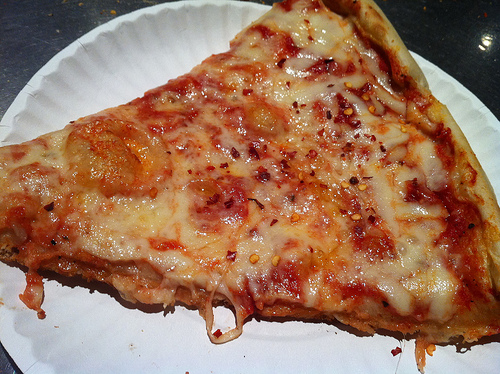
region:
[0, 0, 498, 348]
Pizza on the plate.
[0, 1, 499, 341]
Triangle slice of pizza.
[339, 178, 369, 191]
Spices on the pizza.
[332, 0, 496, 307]
Crust on the pizza.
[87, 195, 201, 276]
cheese on the pizza.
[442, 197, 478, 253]
Red sauce on the pizza.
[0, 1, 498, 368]
White plate under the pizza.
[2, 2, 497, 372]
Grey surface under the plate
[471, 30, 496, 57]
Light shine on the counter.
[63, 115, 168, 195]
cheese bubble on the pizza.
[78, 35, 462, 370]
a pizza on the plate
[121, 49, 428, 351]
it is white in colour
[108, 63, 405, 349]
it has red pigments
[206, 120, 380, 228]
there are seeds on it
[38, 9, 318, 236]
thge plate is white in colour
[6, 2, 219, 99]
the plate is round in shape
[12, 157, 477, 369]
the pizza is cut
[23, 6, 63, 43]
the table is black in colour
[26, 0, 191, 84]
the plates tip is serrated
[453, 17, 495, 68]
the light is on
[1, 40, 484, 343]
one slice of pizza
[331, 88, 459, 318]
cheese is melted in pizza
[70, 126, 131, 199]
pepperoni in between cheese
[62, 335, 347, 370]
plate is white under foiod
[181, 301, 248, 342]
cheese is partly hanging onto plate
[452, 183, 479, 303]
red sauce is mixed in with pizza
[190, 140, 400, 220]
seasoning is scattered on top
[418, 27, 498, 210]
crust is thin and well done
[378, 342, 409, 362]
crumb on the plate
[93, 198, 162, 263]
thick layer of cheese